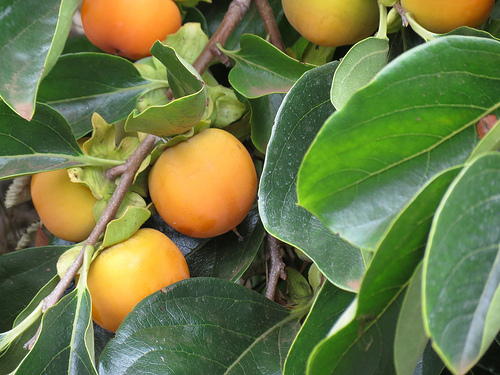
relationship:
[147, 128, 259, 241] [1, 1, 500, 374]
fruit on tree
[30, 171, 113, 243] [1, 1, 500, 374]
fruit on tree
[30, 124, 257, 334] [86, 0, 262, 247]
fruits on branch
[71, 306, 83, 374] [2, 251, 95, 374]
reflection on leaves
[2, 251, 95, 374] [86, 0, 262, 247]
leaves on branch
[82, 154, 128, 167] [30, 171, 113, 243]
stem holding fruit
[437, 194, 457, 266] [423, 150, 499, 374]
back of leaf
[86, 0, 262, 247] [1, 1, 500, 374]
branch of tree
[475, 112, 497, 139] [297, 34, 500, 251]
spot on leaf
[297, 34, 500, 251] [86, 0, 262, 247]
leaf on branch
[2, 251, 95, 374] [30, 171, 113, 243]
leaves around fruit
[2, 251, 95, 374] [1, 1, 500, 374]
leaves on tree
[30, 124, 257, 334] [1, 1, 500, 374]
fruits on tree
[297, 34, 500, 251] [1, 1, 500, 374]
leaf on tree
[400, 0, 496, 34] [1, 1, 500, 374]
pear on tree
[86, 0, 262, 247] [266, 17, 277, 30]
branch light brown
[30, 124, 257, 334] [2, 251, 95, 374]
fruits under leaves